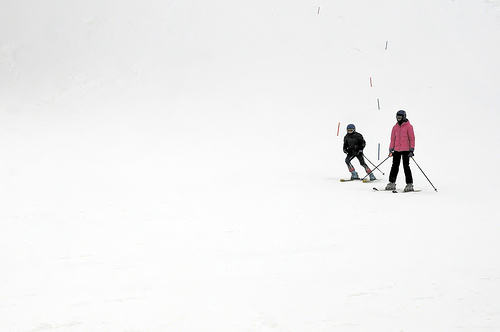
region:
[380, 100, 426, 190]
person in pink jacket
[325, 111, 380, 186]
person in black jacket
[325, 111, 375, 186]
person skiing in snow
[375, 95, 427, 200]
person skiing in snow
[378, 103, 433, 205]
person wearing pink jacket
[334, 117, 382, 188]
person wearing black jacket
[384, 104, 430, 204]
person wearing black hat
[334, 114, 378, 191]
person wearing black hat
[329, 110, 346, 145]
orange pole in snow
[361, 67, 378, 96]
orange pole in snow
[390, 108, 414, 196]
A person wearing a pink coat.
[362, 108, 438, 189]
A person holding ski poles.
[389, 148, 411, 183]
Black pants on a skier.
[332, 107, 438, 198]
Two skiers in ski outfits.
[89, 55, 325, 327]
White snow on the ski slope.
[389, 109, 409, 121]
A helmet on the skiers head.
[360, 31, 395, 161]
Colored poles sticking in the ground.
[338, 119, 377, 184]
A person skiing down the slope.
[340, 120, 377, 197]
A skier with bent knees.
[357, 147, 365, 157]
A glove on the skier's hand.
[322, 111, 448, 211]
some people riding skis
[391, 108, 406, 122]
the head of a kid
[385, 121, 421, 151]
the torso of a kid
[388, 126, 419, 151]
the jacket of a kid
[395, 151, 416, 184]
the left leg of a kid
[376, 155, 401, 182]
the right leg of a kid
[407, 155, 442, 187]
the ski stick of a kid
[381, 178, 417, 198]
the shoes of a kid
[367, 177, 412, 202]
the skis of a kid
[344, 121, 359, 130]
the hat of a kid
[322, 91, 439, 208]
kids with skiing gears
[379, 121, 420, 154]
the jacket is pink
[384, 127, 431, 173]
the jacket is pink